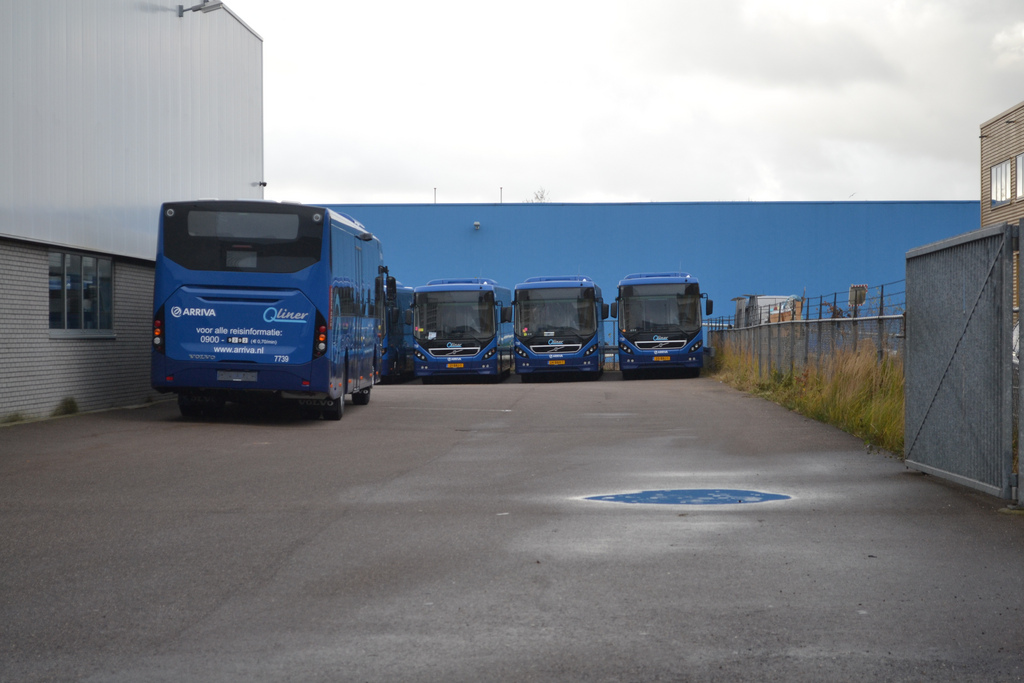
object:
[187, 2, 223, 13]
light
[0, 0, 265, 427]
building